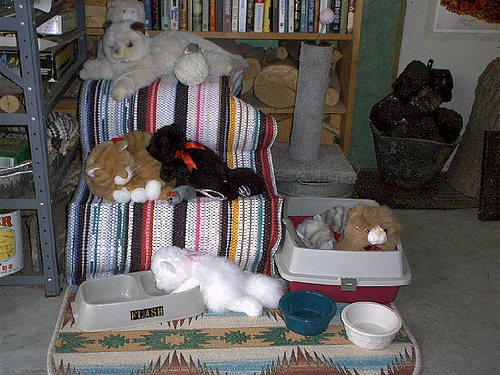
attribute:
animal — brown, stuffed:
[338, 201, 399, 255]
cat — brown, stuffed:
[81, 129, 172, 206]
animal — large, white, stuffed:
[75, 16, 251, 99]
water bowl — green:
[277, 288, 335, 336]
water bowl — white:
[341, 298, 404, 351]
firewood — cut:
[237, 44, 347, 110]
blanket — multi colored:
[63, 77, 282, 279]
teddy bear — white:
[149, 242, 285, 318]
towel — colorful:
[43, 337, 421, 373]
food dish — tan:
[71, 269, 212, 332]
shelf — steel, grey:
[4, 112, 64, 301]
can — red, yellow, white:
[0, 205, 26, 282]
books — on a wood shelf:
[150, 1, 356, 32]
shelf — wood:
[154, 25, 359, 46]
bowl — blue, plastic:
[277, 285, 341, 338]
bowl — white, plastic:
[340, 299, 404, 354]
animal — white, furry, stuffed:
[151, 240, 287, 317]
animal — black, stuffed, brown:
[143, 119, 265, 203]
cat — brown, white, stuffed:
[78, 125, 168, 201]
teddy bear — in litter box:
[337, 199, 400, 255]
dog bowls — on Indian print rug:
[275, 288, 404, 348]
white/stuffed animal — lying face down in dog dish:
[151, 240, 275, 321]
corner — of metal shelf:
[18, 90, 52, 136]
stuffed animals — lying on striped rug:
[81, 16, 265, 202]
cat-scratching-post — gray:
[270, 36, 354, 179]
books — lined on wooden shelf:
[141, 0, 353, 36]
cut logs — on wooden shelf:
[244, 43, 302, 111]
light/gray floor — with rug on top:
[12, 274, 482, 369]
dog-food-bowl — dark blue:
[275, 288, 338, 338]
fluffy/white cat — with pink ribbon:
[149, 245, 279, 322]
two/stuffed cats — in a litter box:
[296, 192, 402, 257]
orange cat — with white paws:
[86, 128, 169, 204]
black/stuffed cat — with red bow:
[144, 120, 266, 202]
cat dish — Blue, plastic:
[276, 285, 336, 336]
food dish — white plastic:
[339, 296, 403, 349]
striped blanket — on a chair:
[65, 67, 288, 288]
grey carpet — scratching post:
[279, 40, 359, 188]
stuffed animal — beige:
[79, 14, 240, 94]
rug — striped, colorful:
[64, 73, 278, 271]